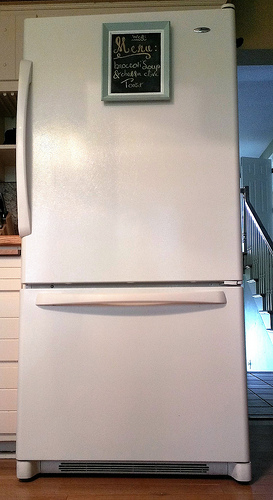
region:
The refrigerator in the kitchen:
[14, 5, 262, 497]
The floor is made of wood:
[10, 475, 244, 497]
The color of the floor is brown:
[53, 475, 173, 498]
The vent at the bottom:
[52, 458, 212, 476]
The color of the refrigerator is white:
[68, 123, 181, 232]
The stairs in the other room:
[242, 190, 271, 363]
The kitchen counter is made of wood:
[0, 229, 23, 272]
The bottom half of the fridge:
[19, 284, 268, 488]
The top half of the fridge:
[16, 10, 246, 287]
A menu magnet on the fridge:
[94, 16, 178, 112]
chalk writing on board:
[97, 33, 162, 103]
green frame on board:
[97, 19, 175, 105]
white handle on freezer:
[34, 286, 209, 309]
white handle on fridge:
[11, 50, 51, 236]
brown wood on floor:
[67, 485, 132, 499]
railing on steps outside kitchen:
[241, 195, 271, 265]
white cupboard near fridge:
[0, 25, 14, 74]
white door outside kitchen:
[238, 158, 267, 239]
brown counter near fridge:
[0, 231, 22, 247]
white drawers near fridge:
[1, 262, 16, 425]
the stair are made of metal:
[245, 203, 272, 289]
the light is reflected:
[247, 315, 271, 373]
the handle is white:
[39, 293, 235, 313]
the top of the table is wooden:
[0, 233, 19, 254]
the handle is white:
[15, 63, 34, 233]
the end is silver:
[192, 24, 212, 36]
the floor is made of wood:
[40, 475, 271, 499]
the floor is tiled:
[248, 369, 272, 416]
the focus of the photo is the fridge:
[1, 15, 272, 489]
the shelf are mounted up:
[1, 2, 43, 83]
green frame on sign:
[93, 15, 167, 115]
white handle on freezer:
[33, 288, 227, 326]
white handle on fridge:
[16, 78, 25, 225]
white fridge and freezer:
[7, 12, 261, 480]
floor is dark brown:
[133, 477, 255, 498]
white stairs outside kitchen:
[239, 211, 272, 327]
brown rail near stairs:
[242, 192, 272, 308]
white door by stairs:
[243, 152, 270, 286]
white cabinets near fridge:
[4, 10, 32, 84]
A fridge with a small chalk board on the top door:
[9, 2, 253, 485]